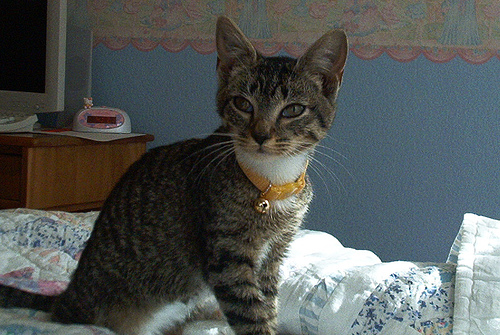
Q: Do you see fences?
A: No, there are no fences.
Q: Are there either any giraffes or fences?
A: No, there are no fences or giraffes.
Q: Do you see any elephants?
A: No, there are no elephants.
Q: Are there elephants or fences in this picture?
A: No, there are no elephants or fences.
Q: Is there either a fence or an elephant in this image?
A: No, there are no elephants or fences.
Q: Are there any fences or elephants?
A: No, there are no elephants or fences.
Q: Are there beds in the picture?
A: Yes, there is a bed.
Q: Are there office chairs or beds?
A: Yes, there is a bed.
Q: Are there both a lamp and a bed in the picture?
A: No, there is a bed but no lamps.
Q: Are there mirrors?
A: No, there are no mirrors.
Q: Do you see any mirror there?
A: No, there are no mirrors.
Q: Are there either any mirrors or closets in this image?
A: No, there are no mirrors or closets.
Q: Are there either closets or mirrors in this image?
A: No, there are no mirrors or closets.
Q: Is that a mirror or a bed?
A: That is a bed.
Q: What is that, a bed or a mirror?
A: That is a bed.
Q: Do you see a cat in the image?
A: Yes, there is a cat.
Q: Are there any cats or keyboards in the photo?
A: Yes, there is a cat.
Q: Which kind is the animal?
A: The animal is a cat.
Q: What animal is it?
A: The animal is a cat.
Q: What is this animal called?
A: This is a cat.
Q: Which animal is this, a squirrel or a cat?
A: This is a cat.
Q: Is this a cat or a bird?
A: This is a cat.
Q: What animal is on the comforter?
A: The cat is on the comforter.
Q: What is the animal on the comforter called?
A: The animal is a cat.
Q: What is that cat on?
A: The cat is on the bed cover.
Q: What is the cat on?
A: The cat is on the bed cover.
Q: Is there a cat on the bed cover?
A: Yes, there is a cat on the bed cover.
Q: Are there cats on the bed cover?
A: Yes, there is a cat on the bed cover.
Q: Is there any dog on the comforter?
A: No, there is a cat on the comforter.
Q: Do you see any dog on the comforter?
A: No, there is a cat on the comforter.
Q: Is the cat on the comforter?
A: Yes, the cat is on the comforter.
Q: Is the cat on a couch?
A: No, the cat is on the comforter.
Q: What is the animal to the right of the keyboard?
A: The animal is a cat.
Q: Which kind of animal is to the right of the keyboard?
A: The animal is a cat.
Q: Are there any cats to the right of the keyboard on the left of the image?
A: Yes, there is a cat to the right of the keyboard.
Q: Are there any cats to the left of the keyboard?
A: No, the cat is to the right of the keyboard.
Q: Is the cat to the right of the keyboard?
A: Yes, the cat is to the right of the keyboard.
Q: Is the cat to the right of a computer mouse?
A: No, the cat is to the right of the keyboard.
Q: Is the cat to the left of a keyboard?
A: No, the cat is to the right of a keyboard.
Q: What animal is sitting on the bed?
A: The cat is sitting on the bed.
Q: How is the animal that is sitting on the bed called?
A: The animal is a cat.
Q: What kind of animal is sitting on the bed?
A: The animal is a cat.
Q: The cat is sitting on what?
A: The cat is sitting on the bed.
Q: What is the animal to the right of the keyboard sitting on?
A: The cat is sitting on the bed.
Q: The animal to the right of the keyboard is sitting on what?
A: The cat is sitting on the bed.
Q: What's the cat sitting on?
A: The cat is sitting on the bed.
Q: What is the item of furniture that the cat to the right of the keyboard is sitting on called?
A: The piece of furniture is a bed.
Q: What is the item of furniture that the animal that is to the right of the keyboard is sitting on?
A: The piece of furniture is a bed.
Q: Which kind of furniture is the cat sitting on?
A: The cat is sitting on the bed.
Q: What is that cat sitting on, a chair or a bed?
A: The cat is sitting on a bed.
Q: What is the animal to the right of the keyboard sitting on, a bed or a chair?
A: The cat is sitting on a bed.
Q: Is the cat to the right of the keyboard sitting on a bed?
A: Yes, the cat is sitting on a bed.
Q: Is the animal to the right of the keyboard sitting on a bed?
A: Yes, the cat is sitting on a bed.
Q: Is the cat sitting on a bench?
A: No, the cat is sitting on a bed.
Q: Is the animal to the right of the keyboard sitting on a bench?
A: No, the cat is sitting on a bed.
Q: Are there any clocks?
A: Yes, there is a clock.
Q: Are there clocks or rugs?
A: Yes, there is a clock.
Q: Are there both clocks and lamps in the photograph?
A: No, there is a clock but no lamps.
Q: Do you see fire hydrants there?
A: No, there are no fire hydrants.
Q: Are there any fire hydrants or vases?
A: No, there are no fire hydrants or vases.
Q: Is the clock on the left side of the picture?
A: Yes, the clock is on the left of the image.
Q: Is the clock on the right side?
A: No, the clock is on the left of the image.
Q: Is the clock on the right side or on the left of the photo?
A: The clock is on the left of the image.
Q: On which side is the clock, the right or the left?
A: The clock is on the left of the image.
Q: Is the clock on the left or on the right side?
A: The clock is on the left of the image.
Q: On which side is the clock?
A: The clock is on the left of the image.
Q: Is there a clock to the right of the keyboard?
A: Yes, there is a clock to the right of the keyboard.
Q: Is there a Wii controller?
A: No, there are no Wii controllers.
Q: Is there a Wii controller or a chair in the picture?
A: No, there are no Wii controllers or chairs.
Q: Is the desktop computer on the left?
A: Yes, the desktop computer is on the left of the image.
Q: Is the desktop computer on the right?
A: No, the desktop computer is on the left of the image.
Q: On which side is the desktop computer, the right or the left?
A: The desktop computer is on the left of the image.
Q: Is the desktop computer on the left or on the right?
A: The desktop computer is on the left of the image.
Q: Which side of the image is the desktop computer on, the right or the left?
A: The desktop computer is on the left of the image.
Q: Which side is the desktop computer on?
A: The desktop computer is on the left of the image.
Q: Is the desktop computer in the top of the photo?
A: Yes, the desktop computer is in the top of the image.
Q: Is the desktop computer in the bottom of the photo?
A: No, the desktop computer is in the top of the image.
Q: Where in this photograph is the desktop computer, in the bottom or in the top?
A: The desktop computer is in the top of the image.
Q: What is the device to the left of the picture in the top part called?
A: The device is a desktop computer.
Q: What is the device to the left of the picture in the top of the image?
A: The device is a desktop computer.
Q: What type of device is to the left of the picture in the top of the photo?
A: The device is a desktop computer.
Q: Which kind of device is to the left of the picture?
A: The device is a desktop computer.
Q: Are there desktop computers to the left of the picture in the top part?
A: Yes, there is a desktop computer to the left of the picture.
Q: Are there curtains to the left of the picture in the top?
A: No, there is a desktop computer to the left of the picture.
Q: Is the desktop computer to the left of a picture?
A: Yes, the desktop computer is to the left of a picture.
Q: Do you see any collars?
A: Yes, there is a collar.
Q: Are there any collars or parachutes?
A: Yes, there is a collar.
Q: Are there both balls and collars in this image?
A: No, there is a collar but no balls.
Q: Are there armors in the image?
A: No, there are no armors.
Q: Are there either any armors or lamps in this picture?
A: No, there are no armors or lamps.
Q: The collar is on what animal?
A: The collar is on the cat.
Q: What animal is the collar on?
A: The collar is on the cat.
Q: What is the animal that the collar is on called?
A: The animal is a cat.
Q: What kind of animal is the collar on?
A: The collar is on the cat.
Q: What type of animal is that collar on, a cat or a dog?
A: The collar is on a cat.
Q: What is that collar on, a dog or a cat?
A: The collar is on a cat.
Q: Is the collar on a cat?
A: Yes, the collar is on a cat.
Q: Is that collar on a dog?
A: No, the collar is on a cat.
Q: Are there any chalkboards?
A: No, there are no chalkboards.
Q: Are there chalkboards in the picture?
A: No, there are no chalkboards.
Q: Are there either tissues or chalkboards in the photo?
A: No, there are no chalkboards or tissues.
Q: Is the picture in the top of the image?
A: Yes, the picture is in the top of the image.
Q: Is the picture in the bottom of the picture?
A: No, the picture is in the top of the image.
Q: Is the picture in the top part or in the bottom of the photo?
A: The picture is in the top of the image.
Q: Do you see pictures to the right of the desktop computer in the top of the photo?
A: Yes, there is a picture to the right of the desktop computer.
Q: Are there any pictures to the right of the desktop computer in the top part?
A: Yes, there is a picture to the right of the desktop computer.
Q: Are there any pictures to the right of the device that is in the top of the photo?
A: Yes, there is a picture to the right of the desktop computer.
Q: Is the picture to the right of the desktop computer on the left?
A: Yes, the picture is to the right of the desktop computer.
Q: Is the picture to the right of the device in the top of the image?
A: Yes, the picture is to the right of the desktop computer.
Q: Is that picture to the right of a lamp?
A: No, the picture is to the right of the desktop computer.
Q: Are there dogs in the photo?
A: No, there are no dogs.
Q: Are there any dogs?
A: No, there are no dogs.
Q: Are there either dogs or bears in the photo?
A: No, there are no dogs or bears.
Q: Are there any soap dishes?
A: No, there are no soap dishes.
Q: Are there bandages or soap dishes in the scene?
A: No, there are no soap dishes or bandages.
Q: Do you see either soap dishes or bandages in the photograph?
A: No, there are no soap dishes or bandages.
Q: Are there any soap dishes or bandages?
A: No, there are no soap dishes or bandages.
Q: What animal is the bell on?
A: The bell is on the cat.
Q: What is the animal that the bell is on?
A: The animal is a cat.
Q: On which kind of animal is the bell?
A: The bell is on the cat.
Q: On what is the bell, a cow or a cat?
A: The bell is on a cat.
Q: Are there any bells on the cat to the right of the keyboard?
A: Yes, there is a bell on the cat.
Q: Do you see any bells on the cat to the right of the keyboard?
A: Yes, there is a bell on the cat.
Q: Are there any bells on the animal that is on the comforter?
A: Yes, there is a bell on the cat.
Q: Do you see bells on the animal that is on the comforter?
A: Yes, there is a bell on the cat.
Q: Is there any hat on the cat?
A: No, there is a bell on the cat.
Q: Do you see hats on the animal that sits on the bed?
A: No, there is a bell on the cat.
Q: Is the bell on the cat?
A: Yes, the bell is on the cat.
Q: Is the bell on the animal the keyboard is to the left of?
A: Yes, the bell is on the cat.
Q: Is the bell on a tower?
A: No, the bell is on the cat.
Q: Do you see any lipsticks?
A: No, there are no lipsticks.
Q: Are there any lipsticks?
A: No, there are no lipsticks.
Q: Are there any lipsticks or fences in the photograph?
A: No, there are no lipsticks or fences.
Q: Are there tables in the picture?
A: Yes, there is a table.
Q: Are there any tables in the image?
A: Yes, there is a table.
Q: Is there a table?
A: Yes, there is a table.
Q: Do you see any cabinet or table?
A: Yes, there is a table.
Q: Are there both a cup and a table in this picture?
A: No, there is a table but no cups.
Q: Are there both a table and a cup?
A: No, there is a table but no cups.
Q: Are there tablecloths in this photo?
A: No, there are no tablecloths.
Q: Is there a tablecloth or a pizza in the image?
A: No, there are no tablecloths or pizzas.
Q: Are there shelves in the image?
A: No, there are no shelves.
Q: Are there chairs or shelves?
A: No, there are no shelves or chairs.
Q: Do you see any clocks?
A: Yes, there is a clock.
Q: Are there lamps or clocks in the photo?
A: Yes, there is a clock.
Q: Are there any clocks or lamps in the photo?
A: Yes, there is a clock.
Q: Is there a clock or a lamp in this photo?
A: Yes, there is a clock.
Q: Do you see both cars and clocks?
A: No, there is a clock but no cars.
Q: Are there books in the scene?
A: No, there are no books.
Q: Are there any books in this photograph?
A: No, there are no books.